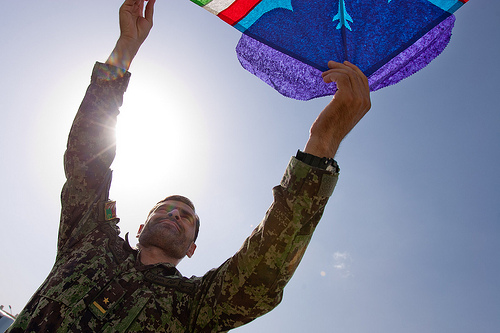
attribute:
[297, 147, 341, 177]
watch — black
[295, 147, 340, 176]
wristband — black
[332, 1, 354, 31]
plane image — blue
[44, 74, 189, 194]
sun — round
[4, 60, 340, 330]
army uniform — green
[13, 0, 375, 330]
man — adult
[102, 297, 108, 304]
star — yellow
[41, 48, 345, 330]
man — adult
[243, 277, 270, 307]
leaf — green